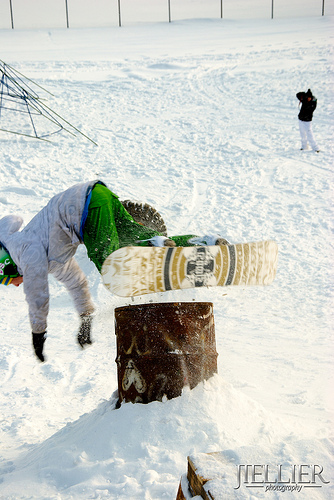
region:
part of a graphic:
[248, 453, 291, 484]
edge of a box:
[181, 458, 202, 487]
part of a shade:
[117, 427, 149, 468]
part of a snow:
[191, 421, 224, 451]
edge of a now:
[114, 428, 144, 471]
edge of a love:
[130, 370, 157, 401]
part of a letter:
[226, 460, 257, 491]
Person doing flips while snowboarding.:
[2, 184, 300, 362]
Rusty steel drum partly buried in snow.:
[105, 296, 225, 426]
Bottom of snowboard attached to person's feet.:
[99, 231, 292, 294]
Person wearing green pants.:
[76, 183, 196, 272]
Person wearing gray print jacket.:
[2, 173, 96, 328]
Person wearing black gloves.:
[31, 310, 99, 364]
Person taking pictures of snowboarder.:
[281, 82, 330, 168]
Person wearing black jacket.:
[293, 91, 316, 124]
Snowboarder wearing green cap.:
[0, 248, 19, 284]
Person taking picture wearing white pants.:
[297, 114, 328, 157]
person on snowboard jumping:
[1, 174, 248, 403]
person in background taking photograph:
[283, 70, 327, 169]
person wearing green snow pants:
[56, 160, 195, 304]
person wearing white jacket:
[2, 189, 99, 342]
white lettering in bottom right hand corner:
[233, 444, 324, 497]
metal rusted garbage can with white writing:
[105, 307, 255, 416]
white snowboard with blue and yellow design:
[103, 240, 275, 311]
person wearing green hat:
[0, 247, 18, 296]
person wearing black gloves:
[15, 284, 115, 388]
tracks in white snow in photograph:
[133, 65, 259, 145]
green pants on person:
[88, 190, 152, 252]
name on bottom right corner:
[236, 437, 324, 497]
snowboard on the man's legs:
[115, 225, 269, 289]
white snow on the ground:
[32, 382, 98, 446]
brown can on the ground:
[108, 289, 222, 398]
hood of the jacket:
[0, 199, 59, 248]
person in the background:
[278, 69, 326, 136]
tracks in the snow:
[156, 102, 222, 157]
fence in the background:
[52, 1, 150, 30]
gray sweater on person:
[0, 176, 84, 272]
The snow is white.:
[123, 76, 247, 163]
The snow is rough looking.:
[131, 93, 233, 166]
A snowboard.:
[90, 233, 286, 301]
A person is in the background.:
[271, 71, 330, 164]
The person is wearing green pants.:
[66, 173, 260, 291]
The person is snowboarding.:
[0, 167, 288, 380]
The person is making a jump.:
[1, 176, 290, 364]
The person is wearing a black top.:
[278, 83, 324, 124]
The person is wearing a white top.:
[0, 171, 111, 379]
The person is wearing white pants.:
[284, 116, 326, 159]